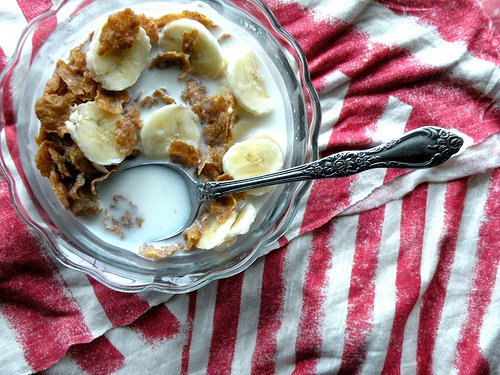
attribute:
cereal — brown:
[86, 23, 276, 240]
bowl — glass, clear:
[18, 23, 332, 291]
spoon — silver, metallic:
[117, 116, 455, 232]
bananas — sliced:
[42, 39, 301, 199]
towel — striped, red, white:
[293, 3, 488, 361]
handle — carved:
[311, 123, 465, 181]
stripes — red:
[341, 209, 490, 365]